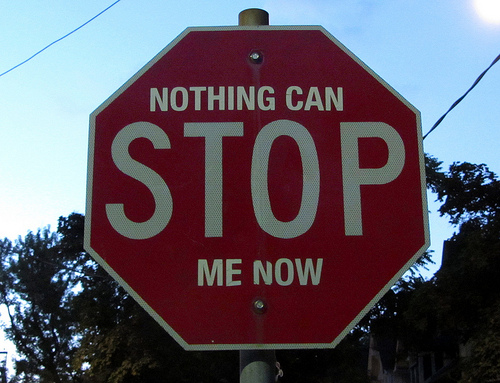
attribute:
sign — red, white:
[84, 22, 430, 353]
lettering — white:
[109, 83, 405, 286]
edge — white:
[189, 25, 322, 33]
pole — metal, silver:
[238, 8, 278, 382]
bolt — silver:
[248, 50, 262, 63]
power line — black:
[0, 1, 125, 87]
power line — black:
[422, 52, 498, 141]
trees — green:
[0, 156, 496, 382]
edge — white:
[317, 23, 423, 111]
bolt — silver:
[254, 300, 270, 315]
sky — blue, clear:
[1, 2, 498, 286]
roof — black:
[370, 315, 464, 350]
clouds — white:
[3, 182, 81, 238]